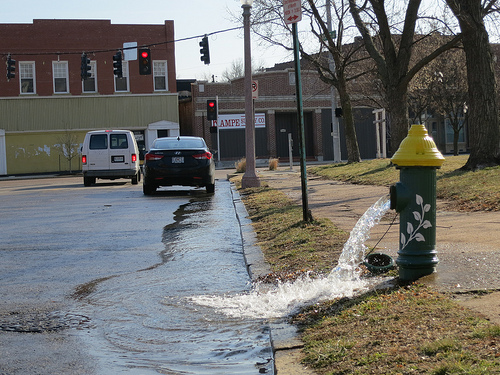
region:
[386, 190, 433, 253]
flower panted on the hydrant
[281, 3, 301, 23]
traffic sign on a pole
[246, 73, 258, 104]
traffic sign on the pole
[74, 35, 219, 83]
traffic lights on the wire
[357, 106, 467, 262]
green and yellow hydrant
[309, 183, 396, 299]
water coming from hydrant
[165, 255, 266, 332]
water on the ground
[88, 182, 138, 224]
shadow next to car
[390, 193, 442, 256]
flower on the hydrant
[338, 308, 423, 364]
grass on the ground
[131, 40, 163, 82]
red light above land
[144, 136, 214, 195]
back of the car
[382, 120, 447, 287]
fire hydrant on sidewalk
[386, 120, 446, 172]
top of hydrant is yellow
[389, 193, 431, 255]
plant painted on hydrant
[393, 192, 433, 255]
plant on hydrant is white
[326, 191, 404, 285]
water pouring from hydrant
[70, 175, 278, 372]
large puddle of water on road side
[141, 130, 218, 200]
small car beside sidewalk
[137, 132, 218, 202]
small car is black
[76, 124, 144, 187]
white van at intersection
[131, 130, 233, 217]
this is a car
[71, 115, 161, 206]
this is a car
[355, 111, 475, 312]
this is a fire hydrant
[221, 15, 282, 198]
this is a post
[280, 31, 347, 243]
this is a post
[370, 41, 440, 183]
the bark of a tree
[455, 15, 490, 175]
the bark of a tree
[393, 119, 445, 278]
Fire hydrant with leaf design.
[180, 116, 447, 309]
Water flowing out of hydrant.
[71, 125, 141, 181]
White van with brake lights on.